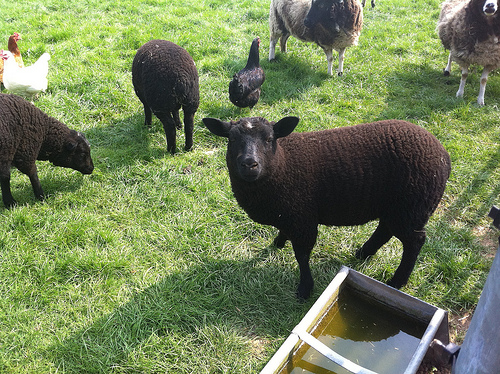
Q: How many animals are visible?
A: Eight.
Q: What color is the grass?
A: Green.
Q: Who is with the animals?
A: No one.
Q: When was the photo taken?
A: Daytime.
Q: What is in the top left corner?
A: Chickens.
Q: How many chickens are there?
A: Three.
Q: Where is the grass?
A: Beneath the animal's feet.